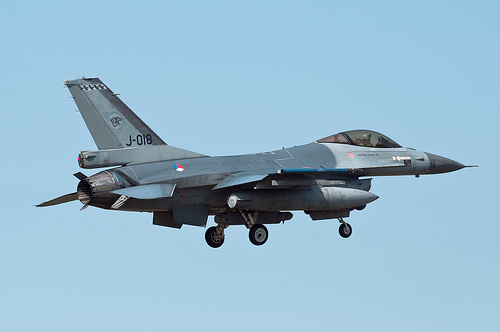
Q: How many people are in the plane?
A: 1.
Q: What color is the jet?
A: Grey.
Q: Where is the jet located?
A: Sky.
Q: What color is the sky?
A: Blue.